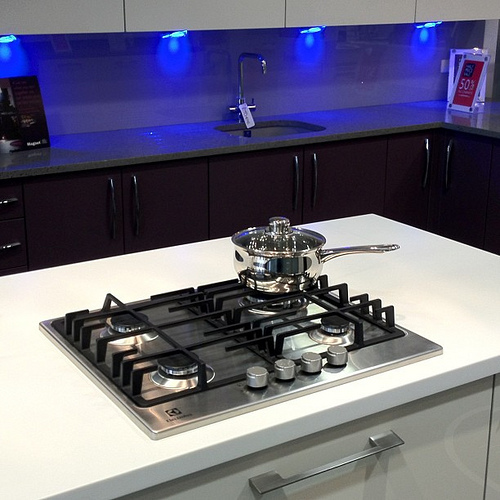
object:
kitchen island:
[0, 211, 500, 500]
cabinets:
[24, 155, 209, 269]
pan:
[231, 215, 398, 294]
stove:
[33, 273, 446, 440]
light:
[160, 31, 188, 39]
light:
[0, 36, 19, 44]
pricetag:
[239, 103, 257, 129]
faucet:
[229, 52, 270, 119]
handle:
[249, 432, 405, 494]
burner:
[148, 349, 214, 391]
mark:
[163, 406, 189, 423]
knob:
[244, 366, 269, 389]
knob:
[274, 359, 297, 380]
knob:
[299, 352, 320, 377]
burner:
[102, 310, 149, 334]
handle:
[314, 244, 401, 264]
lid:
[233, 215, 322, 251]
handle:
[294, 152, 301, 215]